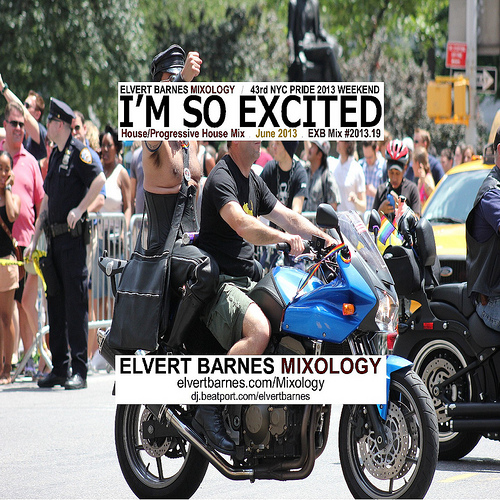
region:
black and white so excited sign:
[112, 74, 389, 146]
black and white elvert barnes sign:
[115, 350, 393, 412]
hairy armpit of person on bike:
[134, 144, 191, 181]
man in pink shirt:
[9, 114, 40, 242]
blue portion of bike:
[268, 257, 403, 329]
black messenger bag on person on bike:
[89, 167, 203, 352]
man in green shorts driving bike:
[198, 154, 312, 327]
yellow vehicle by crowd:
[423, 151, 485, 286]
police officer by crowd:
[18, 93, 94, 400]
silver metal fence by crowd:
[75, 192, 162, 312]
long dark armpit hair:
[149, 149, 161, 169]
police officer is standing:
[18, 96, 104, 389]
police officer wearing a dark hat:
[41, 95, 76, 122]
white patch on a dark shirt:
[77, 148, 94, 165]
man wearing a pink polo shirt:
[0, 100, 42, 381]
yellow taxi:
[423, 158, 495, 283]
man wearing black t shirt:
[197, 153, 277, 274]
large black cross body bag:
[106, 140, 176, 352]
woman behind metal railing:
[91, 213, 148, 331]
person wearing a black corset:
[141, 181, 203, 252]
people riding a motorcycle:
[10, 45, 448, 490]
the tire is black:
[322, 350, 452, 484]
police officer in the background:
[14, 87, 99, 387]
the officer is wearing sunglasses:
[37, 105, 78, 137]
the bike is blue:
[227, 184, 391, 343]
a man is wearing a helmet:
[353, 127, 419, 187]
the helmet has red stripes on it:
[370, 132, 417, 175]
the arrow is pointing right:
[448, 62, 498, 90]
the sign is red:
[432, 28, 469, 72]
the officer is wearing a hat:
[32, 90, 85, 138]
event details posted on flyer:
[119, 80, 384, 140]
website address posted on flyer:
[117, 356, 387, 404]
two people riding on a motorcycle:
[128, 48, 450, 480]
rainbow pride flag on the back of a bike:
[375, 210, 399, 247]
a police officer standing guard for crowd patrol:
[28, 93, 104, 391]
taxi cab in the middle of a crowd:
[404, 138, 496, 260]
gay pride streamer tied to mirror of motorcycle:
[291, 239, 364, 309]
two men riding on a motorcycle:
[130, 43, 352, 428]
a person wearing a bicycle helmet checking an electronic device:
[371, 137, 420, 224]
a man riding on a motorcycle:
[406, 96, 498, 432]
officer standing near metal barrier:
[35, 97, 91, 386]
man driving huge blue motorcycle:
[180, 122, 339, 448]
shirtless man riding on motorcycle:
[131, 45, 216, 365]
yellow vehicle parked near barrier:
[406, 159, 498, 289]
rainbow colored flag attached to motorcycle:
[375, 208, 418, 265]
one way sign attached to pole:
[451, 67, 497, 89]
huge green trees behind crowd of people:
[0, 0, 442, 144]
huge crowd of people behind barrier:
[4, 75, 471, 392]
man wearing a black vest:
[463, 134, 498, 343]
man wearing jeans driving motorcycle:
[454, 130, 498, 340]